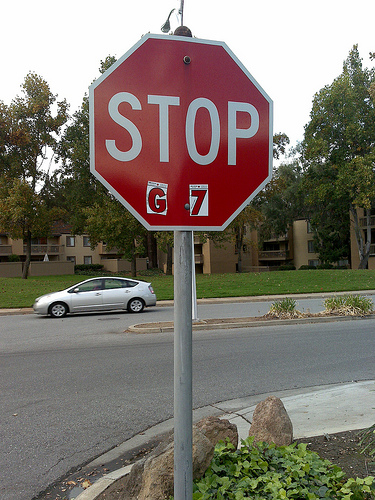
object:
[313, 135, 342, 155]
green leaves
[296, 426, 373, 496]
dirt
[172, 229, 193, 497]
pole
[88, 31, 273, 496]
sign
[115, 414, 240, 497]
rocks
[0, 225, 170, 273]
apartment building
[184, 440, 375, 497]
bush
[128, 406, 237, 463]
curb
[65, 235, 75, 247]
window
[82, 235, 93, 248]
window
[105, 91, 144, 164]
letter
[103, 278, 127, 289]
windows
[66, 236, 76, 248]
windows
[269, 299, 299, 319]
bush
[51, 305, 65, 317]
rims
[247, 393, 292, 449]
rock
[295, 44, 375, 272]
tree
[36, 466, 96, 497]
water puddle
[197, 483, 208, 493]
leaves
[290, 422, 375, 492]
ground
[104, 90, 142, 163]
s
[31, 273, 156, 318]
car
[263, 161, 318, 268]
trees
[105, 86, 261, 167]
stop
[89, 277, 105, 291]
person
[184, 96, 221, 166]
letter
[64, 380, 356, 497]
curve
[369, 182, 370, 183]
leaves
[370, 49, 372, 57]
leaves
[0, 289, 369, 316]
curb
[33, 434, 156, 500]
curb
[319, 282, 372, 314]
bush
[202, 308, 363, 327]
ground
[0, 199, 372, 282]
building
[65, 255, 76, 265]
window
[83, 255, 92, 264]
window